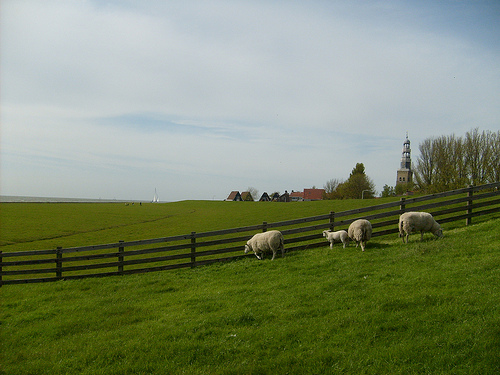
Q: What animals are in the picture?
A: Sheep.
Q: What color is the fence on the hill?
A: Gray.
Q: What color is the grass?
A: Green.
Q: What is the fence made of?
A: Wood.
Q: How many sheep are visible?
A: Four.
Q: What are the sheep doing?
A: Grazing the grass.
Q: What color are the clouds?
A: White.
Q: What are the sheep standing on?
A: Grass.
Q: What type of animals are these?
A: Sheep.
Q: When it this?
A: Daytime.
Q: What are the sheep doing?
A: Eating.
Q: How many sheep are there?
A: Four.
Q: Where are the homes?
A: At the top of the hill.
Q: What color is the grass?
A: Green.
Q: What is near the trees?
A: A tower.